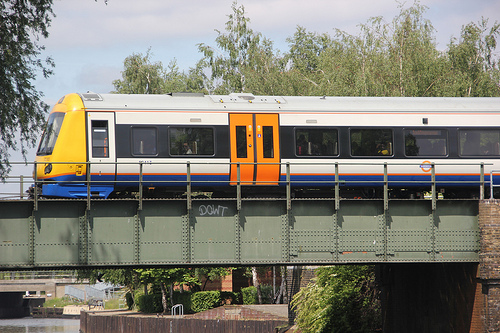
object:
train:
[23, 87, 500, 198]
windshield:
[32, 109, 70, 158]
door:
[224, 111, 284, 190]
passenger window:
[166, 126, 217, 159]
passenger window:
[293, 125, 344, 159]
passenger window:
[348, 126, 397, 159]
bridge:
[2, 159, 500, 275]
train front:
[28, 90, 92, 182]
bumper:
[32, 179, 118, 201]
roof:
[76, 88, 500, 111]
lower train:
[58, 170, 500, 189]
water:
[1, 310, 84, 332]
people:
[292, 132, 311, 156]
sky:
[2, 0, 499, 198]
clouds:
[27, 3, 499, 59]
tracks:
[1, 191, 498, 203]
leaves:
[150, 273, 164, 284]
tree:
[138, 262, 179, 318]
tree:
[1, 2, 60, 184]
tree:
[440, 3, 498, 100]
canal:
[1, 287, 127, 331]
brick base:
[459, 195, 498, 331]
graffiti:
[192, 200, 233, 221]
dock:
[80, 297, 296, 320]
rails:
[173, 304, 185, 316]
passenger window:
[402, 127, 451, 160]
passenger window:
[456, 127, 500, 159]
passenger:
[177, 138, 196, 157]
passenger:
[374, 140, 391, 157]